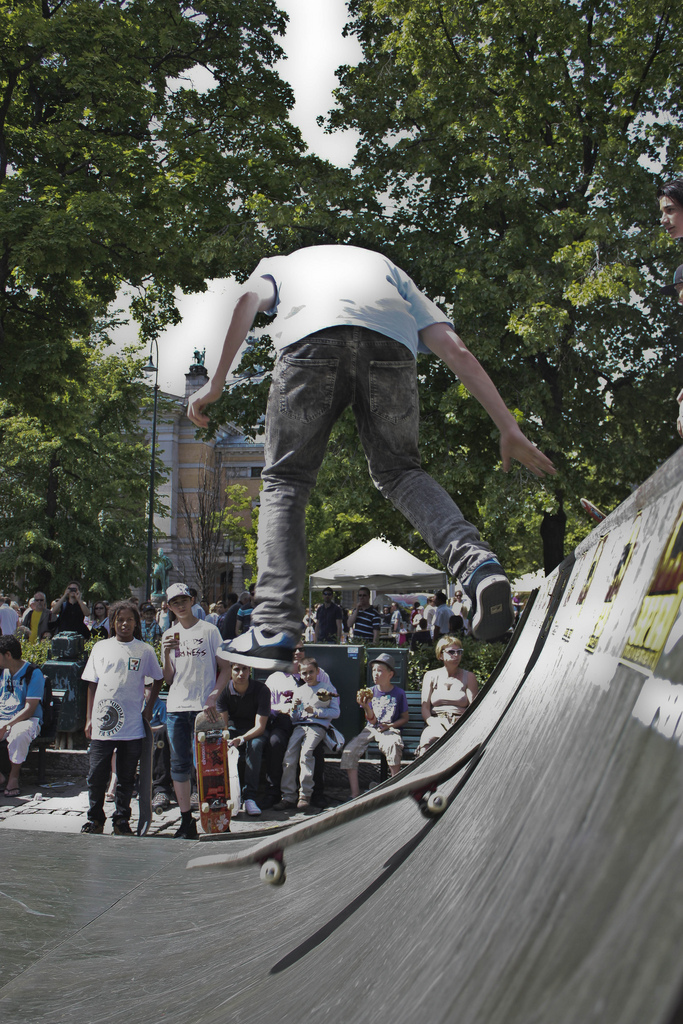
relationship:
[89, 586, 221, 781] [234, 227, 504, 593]
people watching man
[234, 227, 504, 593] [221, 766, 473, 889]
man on board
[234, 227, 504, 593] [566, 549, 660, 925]
man on ramp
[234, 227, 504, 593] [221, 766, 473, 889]
man using board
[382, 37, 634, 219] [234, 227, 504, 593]
tree near man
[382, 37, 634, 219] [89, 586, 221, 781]
tree next to people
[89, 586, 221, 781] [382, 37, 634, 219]
people next to tree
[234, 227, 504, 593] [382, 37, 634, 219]
man near tree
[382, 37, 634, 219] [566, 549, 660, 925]
tree next to ramp